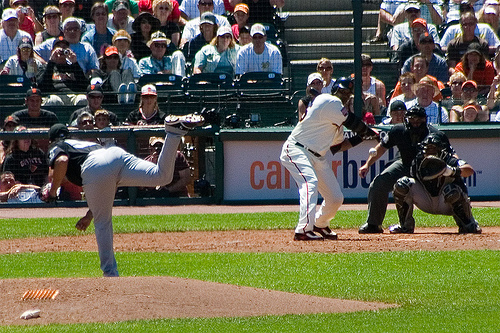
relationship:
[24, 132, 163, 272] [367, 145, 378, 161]
pitcher throws ball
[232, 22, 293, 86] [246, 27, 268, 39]
man wears sunglasses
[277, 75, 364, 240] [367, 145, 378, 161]
players hits ball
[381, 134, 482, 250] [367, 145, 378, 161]
catcher catches ball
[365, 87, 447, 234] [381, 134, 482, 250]
umpire behind catcher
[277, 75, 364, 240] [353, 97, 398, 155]
players swings bat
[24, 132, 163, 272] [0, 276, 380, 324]
pitcher on mound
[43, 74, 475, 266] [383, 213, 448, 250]
players at home plate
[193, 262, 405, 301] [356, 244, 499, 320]
grass on field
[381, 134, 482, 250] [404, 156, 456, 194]
catcher has mitt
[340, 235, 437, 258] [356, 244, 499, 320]
dirt on field